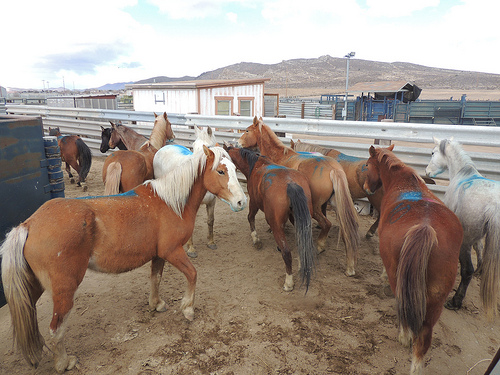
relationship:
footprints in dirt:
[138, 232, 431, 373] [1, 149, 499, 369]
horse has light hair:
[154, 121, 217, 177] [184, 127, 205, 156]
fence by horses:
[7, 103, 499, 208] [15, 119, 499, 346]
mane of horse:
[146, 143, 228, 219] [4, 150, 248, 352]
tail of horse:
[5, 214, 40, 316] [4, 150, 248, 352]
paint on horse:
[461, 173, 494, 190] [426, 137, 499, 304]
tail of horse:
[286, 184, 318, 280] [238, 141, 315, 284]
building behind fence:
[129, 77, 263, 115] [7, 103, 499, 208]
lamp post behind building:
[343, 52, 358, 121] [129, 77, 263, 115]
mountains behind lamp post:
[96, 50, 499, 101] [343, 52, 358, 121]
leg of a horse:
[266, 219, 301, 290] [238, 141, 315, 284]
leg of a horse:
[158, 255, 197, 316] [4, 150, 248, 352]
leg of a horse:
[462, 239, 481, 313] [426, 137, 499, 304]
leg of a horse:
[40, 272, 84, 371] [4, 150, 248, 352]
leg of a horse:
[148, 255, 171, 313] [4, 150, 248, 352]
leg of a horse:
[71, 155, 86, 187] [50, 126, 95, 175]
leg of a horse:
[384, 262, 413, 343] [355, 148, 455, 352]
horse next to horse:
[355, 148, 455, 352] [237, 120, 359, 275]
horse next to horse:
[355, 148, 455, 352] [238, 141, 315, 284]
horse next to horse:
[4, 150, 248, 352] [238, 141, 315, 284]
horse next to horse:
[238, 141, 315, 284] [355, 148, 455, 352]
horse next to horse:
[237, 120, 359, 275] [4, 150, 248, 352]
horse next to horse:
[238, 141, 315, 284] [4, 150, 248, 352]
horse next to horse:
[355, 148, 455, 352] [4, 150, 248, 352]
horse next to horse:
[237, 120, 359, 275] [355, 148, 455, 352]